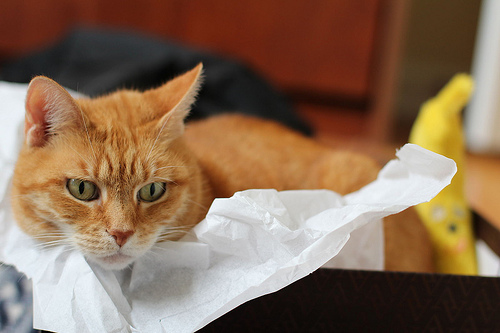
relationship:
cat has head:
[3, 30, 251, 275] [25, 104, 192, 237]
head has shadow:
[25, 104, 192, 237] [141, 274, 205, 307]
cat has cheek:
[3, 30, 251, 275] [50, 204, 104, 265]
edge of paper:
[430, 152, 461, 190] [325, 136, 441, 244]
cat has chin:
[3, 30, 251, 275] [109, 251, 149, 291]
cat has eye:
[4, 67, 445, 287] [58, 165, 119, 222]